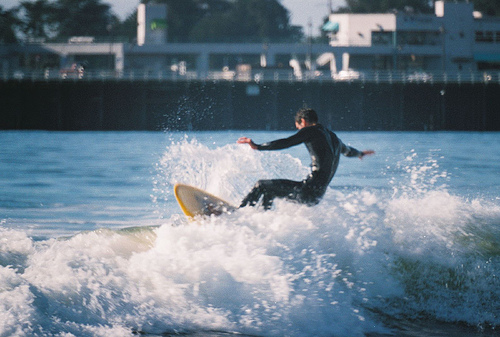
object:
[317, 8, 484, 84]
building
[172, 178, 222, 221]
board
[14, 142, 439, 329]
water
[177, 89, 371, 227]
man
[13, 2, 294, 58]
trees